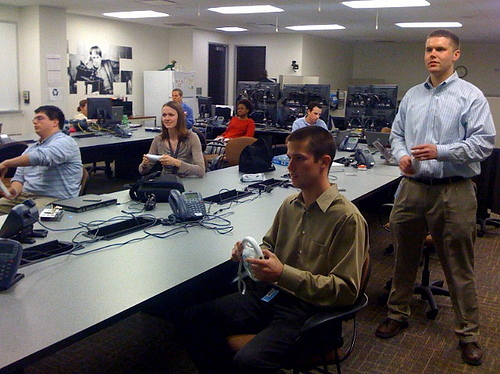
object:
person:
[375, 28, 496, 362]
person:
[138, 102, 205, 175]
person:
[0, 105, 85, 201]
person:
[206, 100, 253, 165]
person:
[287, 100, 331, 136]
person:
[168, 84, 196, 129]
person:
[228, 126, 374, 372]